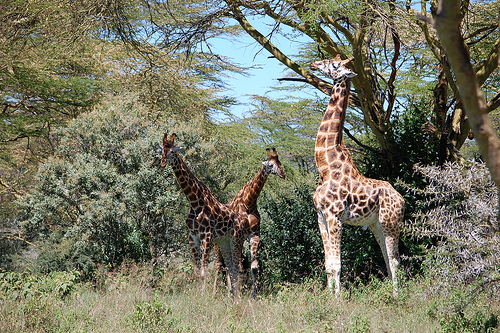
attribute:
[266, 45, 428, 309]
giraffe — tall, statuesque, brown, proper, three, standing, streching, walking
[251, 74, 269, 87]
sky — blue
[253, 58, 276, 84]
skies — clear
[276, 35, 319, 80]
leaves — gray, green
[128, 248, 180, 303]
twigs — dry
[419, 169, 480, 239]
flowers — red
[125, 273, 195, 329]
grass — long, green, tall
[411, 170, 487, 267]
bush — purple